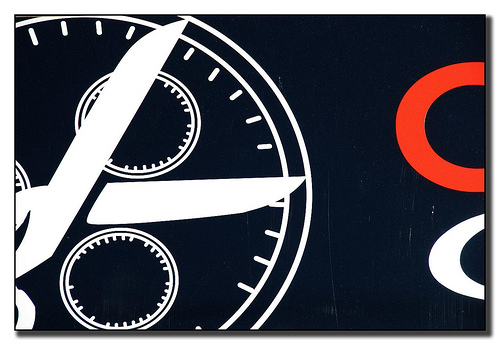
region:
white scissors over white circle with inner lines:
[16, 21, 301, 218]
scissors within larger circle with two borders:
[20, 15, 310, 325]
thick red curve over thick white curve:
[395, 61, 480, 301]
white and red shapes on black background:
[21, 26, 481, 331]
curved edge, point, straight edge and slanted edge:
[80, 171, 305, 226]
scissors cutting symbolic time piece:
[15, 17, 305, 322]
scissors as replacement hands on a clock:
[16, 20, 302, 322]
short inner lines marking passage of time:
[17, 20, 283, 325]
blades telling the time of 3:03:
[65, 20, 300, 245]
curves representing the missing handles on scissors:
[18, 62, 483, 323]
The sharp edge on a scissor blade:
[281, 168, 308, 194]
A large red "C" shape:
[467, 58, 484, 87]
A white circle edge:
[240, 45, 263, 72]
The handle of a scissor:
[15, 305, 37, 328]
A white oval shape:
[464, 221, 482, 239]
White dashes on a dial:
[244, 115, 264, 125]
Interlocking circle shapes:
[158, 274, 183, 296]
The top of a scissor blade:
[163, 17, 190, 41]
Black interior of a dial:
[27, 81, 52, 108]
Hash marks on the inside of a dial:
[177, 91, 188, 111]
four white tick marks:
[179, 46, 271, 131]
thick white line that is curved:
[417, 204, 490, 302]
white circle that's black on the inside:
[51, 228, 189, 332]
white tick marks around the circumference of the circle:
[53, 223, 192, 335]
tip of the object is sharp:
[289, 167, 310, 192]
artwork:
[15, 18, 496, 335]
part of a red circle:
[380, 43, 488, 197]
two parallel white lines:
[197, 22, 326, 342]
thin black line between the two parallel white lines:
[62, 221, 189, 328]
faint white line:
[319, 163, 351, 331]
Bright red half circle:
[389, 44, 493, 196]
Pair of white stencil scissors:
[13, 17, 310, 334]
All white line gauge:
[13, 13, 323, 337]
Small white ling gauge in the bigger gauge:
[49, 220, 196, 337]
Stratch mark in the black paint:
[312, 178, 376, 339]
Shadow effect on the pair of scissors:
[59, 169, 124, 236]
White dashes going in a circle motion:
[23, 18, 292, 305]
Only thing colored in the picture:
[379, 50, 498, 204]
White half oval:
[416, 206, 495, 309]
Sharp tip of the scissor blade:
[155, 15, 199, 59]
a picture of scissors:
[33, 3, 212, 208]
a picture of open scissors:
[23, 20, 349, 340]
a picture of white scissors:
[28, 18, 225, 252]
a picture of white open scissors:
[29, 23, 328, 343]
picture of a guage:
[34, 25, 389, 344]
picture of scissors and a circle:
[48, 33, 343, 333]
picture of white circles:
[14, 19, 386, 339]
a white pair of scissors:
[83, 55, 381, 340]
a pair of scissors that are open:
[39, 66, 288, 340]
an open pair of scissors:
[28, 23, 362, 312]